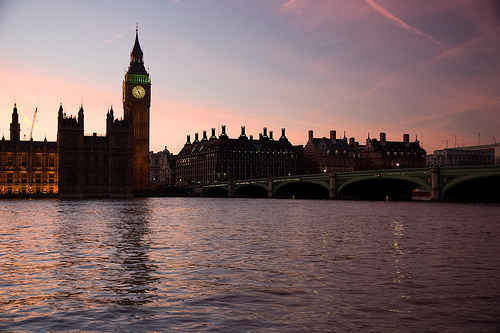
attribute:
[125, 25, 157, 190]
tower — brown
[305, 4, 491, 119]
clouds — white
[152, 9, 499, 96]
sky — blue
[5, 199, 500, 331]
water — calm, dark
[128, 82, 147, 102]
clock — white, light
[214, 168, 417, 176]
lights — on